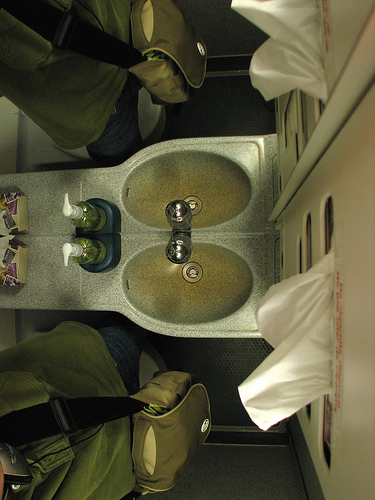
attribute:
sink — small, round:
[118, 230, 256, 326]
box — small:
[2, 234, 38, 292]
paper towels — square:
[1, 236, 11, 264]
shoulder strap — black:
[11, 1, 144, 73]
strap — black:
[1, 393, 149, 453]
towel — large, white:
[235, 246, 336, 435]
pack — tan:
[128, 372, 217, 488]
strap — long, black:
[8, 389, 166, 450]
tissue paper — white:
[237, 248, 336, 431]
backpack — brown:
[5, 0, 210, 109]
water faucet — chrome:
[18, 200, 273, 322]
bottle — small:
[58, 235, 96, 265]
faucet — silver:
[151, 185, 198, 274]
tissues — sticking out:
[205, 36, 335, 159]